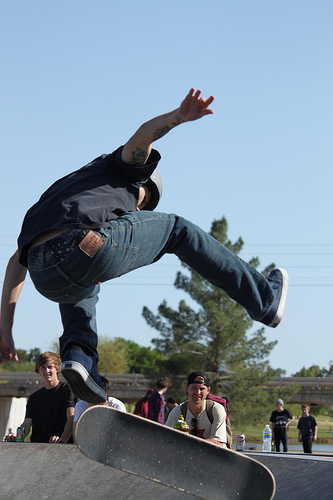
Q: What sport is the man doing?
A: Skateboarding.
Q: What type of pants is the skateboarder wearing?
A: Jeans.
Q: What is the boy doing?
A: Skateboarding.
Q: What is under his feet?
A: A skateboard.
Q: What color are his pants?
A: Blue.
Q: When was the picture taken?
A: In the daytime.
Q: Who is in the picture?
A: Skaters.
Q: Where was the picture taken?
A: In a skate park.